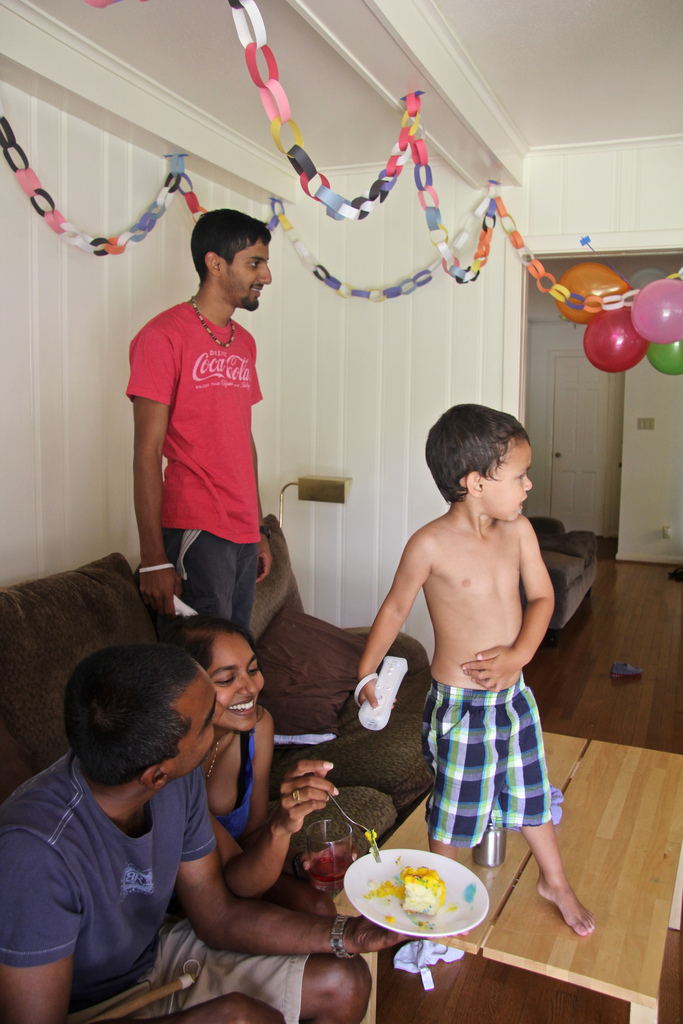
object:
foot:
[536, 871, 597, 936]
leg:
[496, 720, 597, 936]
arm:
[355, 526, 432, 706]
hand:
[351, 662, 379, 708]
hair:
[423, 400, 533, 501]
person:
[354, 403, 595, 932]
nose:
[519, 477, 535, 488]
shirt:
[123, 299, 262, 545]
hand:
[459, 643, 522, 693]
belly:
[427, 600, 522, 685]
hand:
[271, 758, 341, 834]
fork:
[309, 767, 384, 858]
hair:
[60, 644, 207, 791]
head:
[63, 643, 222, 791]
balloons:
[578, 274, 680, 376]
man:
[125, 203, 271, 641]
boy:
[355, 402, 597, 936]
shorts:
[422, 677, 553, 846]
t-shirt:
[1, 750, 219, 1008]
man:
[2, 636, 413, 1020]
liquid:
[306, 848, 348, 883]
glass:
[303, 813, 352, 898]